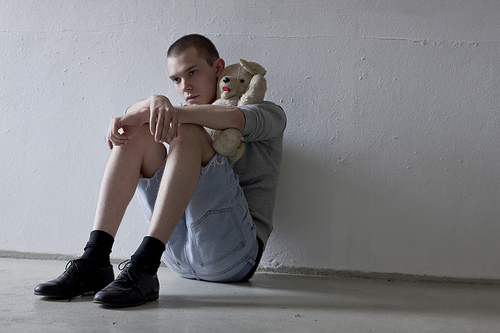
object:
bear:
[200, 59, 266, 161]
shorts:
[129, 150, 259, 283]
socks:
[128, 235, 164, 272]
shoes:
[93, 260, 162, 308]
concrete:
[0, 250, 499, 332]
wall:
[0, 0, 499, 281]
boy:
[32, 33, 286, 306]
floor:
[0, 254, 499, 332]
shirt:
[196, 101, 287, 251]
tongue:
[220, 85, 230, 92]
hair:
[166, 33, 222, 66]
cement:
[0, 256, 499, 332]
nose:
[222, 77, 230, 84]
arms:
[140, 105, 260, 129]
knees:
[168, 123, 206, 142]